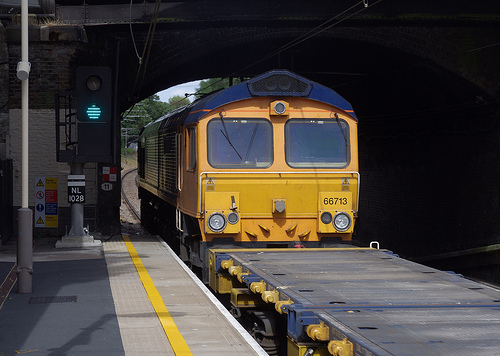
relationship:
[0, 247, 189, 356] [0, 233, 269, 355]
shadow on floor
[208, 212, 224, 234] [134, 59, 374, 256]
headlight on front of train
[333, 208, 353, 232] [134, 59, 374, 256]
headlight on front of train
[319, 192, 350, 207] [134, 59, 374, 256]
numbers on front of train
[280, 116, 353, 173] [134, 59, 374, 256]
window on front of train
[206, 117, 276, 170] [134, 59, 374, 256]
window on front of train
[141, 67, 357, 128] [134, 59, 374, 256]
top of train on train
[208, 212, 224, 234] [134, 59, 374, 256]
headlight on train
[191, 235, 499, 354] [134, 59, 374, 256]
flat bed of train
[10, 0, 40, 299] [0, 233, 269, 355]
post on floor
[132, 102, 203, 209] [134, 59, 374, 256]
side of train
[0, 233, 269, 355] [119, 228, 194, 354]
floor has line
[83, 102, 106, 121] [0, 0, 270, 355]
light on platform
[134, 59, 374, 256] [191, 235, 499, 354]
train has flat bed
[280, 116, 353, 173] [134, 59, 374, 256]
window on train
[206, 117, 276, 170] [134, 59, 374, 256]
window on train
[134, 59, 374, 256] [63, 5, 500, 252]
train emerging from tunnel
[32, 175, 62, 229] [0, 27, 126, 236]
warning sign on wall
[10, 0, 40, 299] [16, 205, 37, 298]
post has concrete base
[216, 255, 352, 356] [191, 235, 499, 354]
bolts on tracks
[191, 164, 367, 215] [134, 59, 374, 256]
handle on train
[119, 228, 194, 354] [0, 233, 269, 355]
line on floor